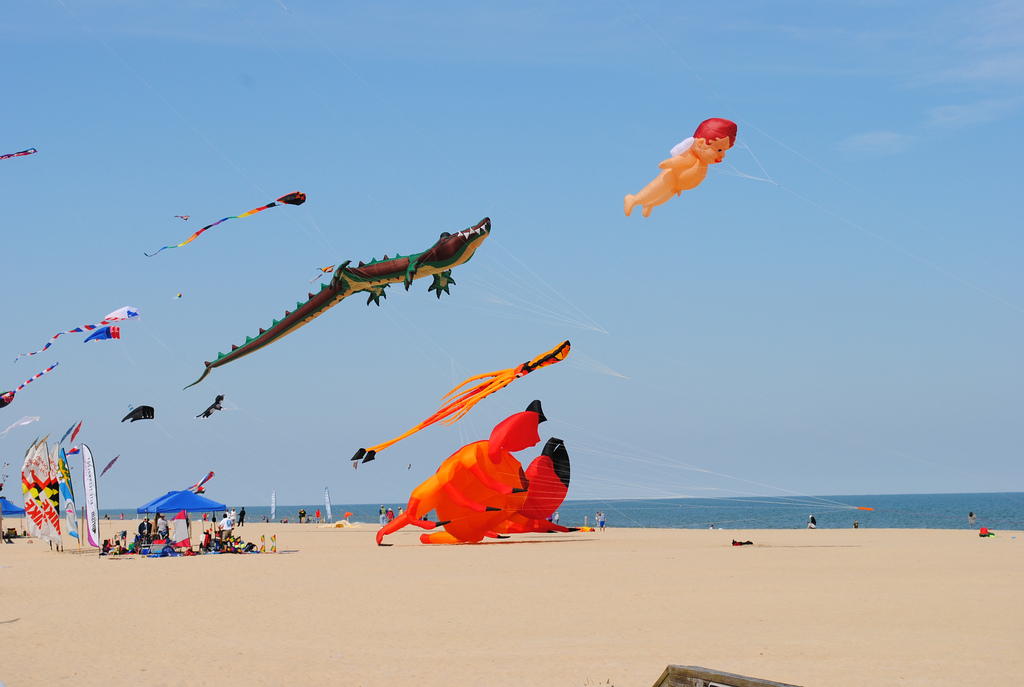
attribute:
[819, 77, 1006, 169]
clouds — white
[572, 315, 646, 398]
clouds — white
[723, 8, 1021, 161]
clouds — white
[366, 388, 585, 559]
kite — scorpion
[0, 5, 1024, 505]
sky — blue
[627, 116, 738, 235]
kite — doll